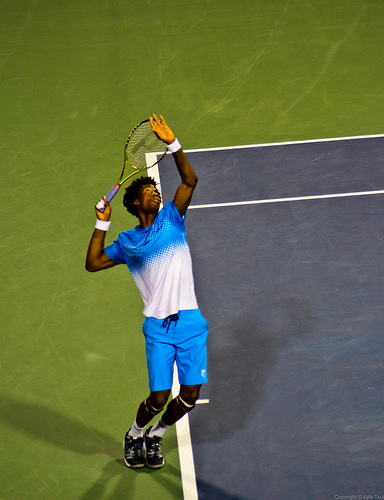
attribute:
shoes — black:
[104, 403, 187, 490]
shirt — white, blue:
[114, 233, 201, 327]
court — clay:
[12, 13, 382, 433]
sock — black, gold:
[137, 384, 190, 438]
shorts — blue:
[121, 294, 253, 405]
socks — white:
[126, 421, 169, 442]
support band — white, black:
[53, 103, 231, 251]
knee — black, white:
[159, 393, 202, 430]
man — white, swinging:
[100, 109, 271, 456]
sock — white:
[124, 421, 143, 438]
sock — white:
[144, 419, 171, 432]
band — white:
[160, 134, 181, 157]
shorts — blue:
[96, 267, 236, 409]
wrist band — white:
[144, 121, 202, 173]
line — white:
[148, 177, 383, 211]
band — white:
[94, 218, 111, 231]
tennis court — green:
[4, 2, 382, 497]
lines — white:
[134, 455, 214, 498]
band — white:
[167, 137, 182, 153]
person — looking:
[96, 124, 212, 407]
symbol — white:
[199, 368, 208, 378]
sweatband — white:
[75, 210, 121, 240]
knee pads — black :
[140, 397, 165, 416]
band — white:
[156, 132, 192, 162]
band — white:
[88, 212, 117, 240]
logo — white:
[199, 369, 206, 378]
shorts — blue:
[139, 307, 210, 390]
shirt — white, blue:
[103, 199, 206, 317]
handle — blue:
[94, 179, 121, 213]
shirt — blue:
[104, 202, 203, 323]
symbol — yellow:
[130, 435, 138, 441]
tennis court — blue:
[142, 130, 382, 495]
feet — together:
[124, 428, 163, 471]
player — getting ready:
[83, 112, 211, 469]